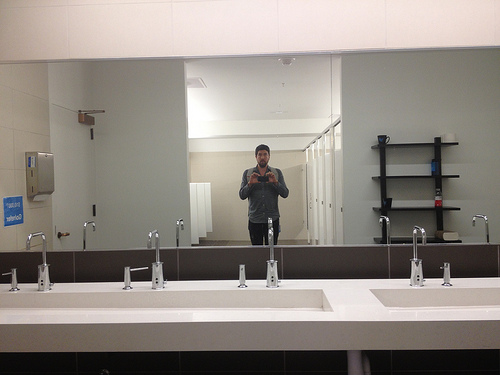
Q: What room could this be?
A: It is a bathroom.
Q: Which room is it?
A: It is a bathroom.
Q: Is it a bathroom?
A: Yes, it is a bathroom.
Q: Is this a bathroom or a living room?
A: It is a bathroom.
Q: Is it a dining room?
A: No, it is a bathroom.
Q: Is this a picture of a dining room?
A: No, the picture is showing a bathroom.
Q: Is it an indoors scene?
A: Yes, it is indoors.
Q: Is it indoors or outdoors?
A: It is indoors.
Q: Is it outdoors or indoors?
A: It is indoors.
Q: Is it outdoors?
A: No, it is indoors.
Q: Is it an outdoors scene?
A: No, it is indoors.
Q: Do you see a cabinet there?
A: No, there are no cabinets.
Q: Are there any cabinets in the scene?
A: No, there are no cabinets.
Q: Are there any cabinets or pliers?
A: No, there are no cabinets or pliers.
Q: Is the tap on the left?
A: Yes, the tap is on the left of the image.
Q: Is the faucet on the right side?
A: No, the faucet is on the left of the image.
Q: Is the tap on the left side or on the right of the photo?
A: The tap is on the left of the image.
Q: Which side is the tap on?
A: The tap is on the left of the image.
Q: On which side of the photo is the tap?
A: The tap is on the left of the image.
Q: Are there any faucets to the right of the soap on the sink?
A: Yes, there is a faucet to the right of the soap.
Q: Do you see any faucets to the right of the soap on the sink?
A: Yes, there is a faucet to the right of the soap.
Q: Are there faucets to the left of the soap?
A: No, the faucet is to the right of the soap.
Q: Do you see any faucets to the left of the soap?
A: No, the faucet is to the right of the soap.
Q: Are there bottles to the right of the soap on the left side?
A: No, there is a faucet to the right of the soap.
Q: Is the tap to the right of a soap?
A: Yes, the tap is to the right of a soap.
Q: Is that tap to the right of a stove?
A: No, the tap is to the right of a soap.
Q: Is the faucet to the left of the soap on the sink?
A: No, the faucet is to the right of the soap.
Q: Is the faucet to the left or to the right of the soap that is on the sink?
A: The faucet is to the right of the soap.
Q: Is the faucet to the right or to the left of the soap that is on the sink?
A: The faucet is to the right of the soap.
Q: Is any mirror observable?
A: Yes, there is a mirror.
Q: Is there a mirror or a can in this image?
A: Yes, there is a mirror.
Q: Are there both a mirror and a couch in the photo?
A: No, there is a mirror but no couches.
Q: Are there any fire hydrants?
A: No, there are no fire hydrants.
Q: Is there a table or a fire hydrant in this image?
A: No, there are no fire hydrants or tables.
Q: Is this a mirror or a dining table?
A: This is a mirror.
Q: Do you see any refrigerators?
A: No, there are no refrigerators.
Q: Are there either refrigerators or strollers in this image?
A: No, there are no refrigerators or strollers.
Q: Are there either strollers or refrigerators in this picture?
A: No, there are no refrigerators or strollers.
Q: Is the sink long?
A: Yes, the sink is long.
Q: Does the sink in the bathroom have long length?
A: Yes, the sink is long.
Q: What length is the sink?
A: The sink is long.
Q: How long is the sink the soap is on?
A: The sink is long.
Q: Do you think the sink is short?
A: No, the sink is long.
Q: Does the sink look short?
A: No, the sink is long.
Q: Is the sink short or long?
A: The sink is long.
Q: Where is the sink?
A: The sink is in the bathroom.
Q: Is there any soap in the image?
A: Yes, there is a soap.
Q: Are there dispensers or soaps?
A: Yes, there is a soap.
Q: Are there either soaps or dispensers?
A: Yes, there is a soap.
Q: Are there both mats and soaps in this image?
A: No, there is a soap but no mats.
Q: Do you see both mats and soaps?
A: No, there is a soap but no mats.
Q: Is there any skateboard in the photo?
A: No, there are no skateboards.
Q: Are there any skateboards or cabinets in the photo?
A: No, there are no skateboards or cabinets.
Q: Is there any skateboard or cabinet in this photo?
A: No, there are no skateboards or cabinets.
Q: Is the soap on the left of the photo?
A: Yes, the soap is on the left of the image.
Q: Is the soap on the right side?
A: No, the soap is on the left of the image.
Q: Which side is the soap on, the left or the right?
A: The soap is on the left of the image.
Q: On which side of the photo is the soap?
A: The soap is on the left of the image.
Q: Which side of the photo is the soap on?
A: The soap is on the left of the image.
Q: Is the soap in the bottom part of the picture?
A: Yes, the soap is in the bottom of the image.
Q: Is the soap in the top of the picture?
A: No, the soap is in the bottom of the image.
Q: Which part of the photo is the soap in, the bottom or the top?
A: The soap is in the bottom of the image.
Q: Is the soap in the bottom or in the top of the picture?
A: The soap is in the bottom of the image.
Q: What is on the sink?
A: The soap is on the sink.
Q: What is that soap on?
A: The soap is on the sink.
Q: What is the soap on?
A: The soap is on the sink.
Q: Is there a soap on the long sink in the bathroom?
A: Yes, there is a soap on the sink.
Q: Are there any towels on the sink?
A: No, there is a soap on the sink.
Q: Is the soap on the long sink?
A: Yes, the soap is on the sink.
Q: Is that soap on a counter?
A: No, the soap is on the sink.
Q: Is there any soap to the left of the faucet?
A: Yes, there is a soap to the left of the faucet.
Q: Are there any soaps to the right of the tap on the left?
A: No, the soap is to the left of the tap.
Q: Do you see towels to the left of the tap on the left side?
A: No, there is a soap to the left of the faucet.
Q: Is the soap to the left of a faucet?
A: Yes, the soap is to the left of a faucet.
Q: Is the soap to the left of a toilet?
A: No, the soap is to the left of a faucet.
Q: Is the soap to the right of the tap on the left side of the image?
A: No, the soap is to the left of the faucet.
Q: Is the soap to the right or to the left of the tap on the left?
A: The soap is to the left of the faucet.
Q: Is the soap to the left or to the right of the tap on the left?
A: The soap is to the left of the faucet.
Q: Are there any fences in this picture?
A: No, there are no fences.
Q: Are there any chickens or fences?
A: No, there are no fences or chickens.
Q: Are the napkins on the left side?
A: Yes, the napkins are on the left of the image.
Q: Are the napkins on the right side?
A: No, the napkins are on the left of the image.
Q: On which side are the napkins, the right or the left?
A: The napkins are on the left of the image.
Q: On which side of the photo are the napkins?
A: The napkins are on the left of the image.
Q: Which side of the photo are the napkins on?
A: The napkins are on the left of the image.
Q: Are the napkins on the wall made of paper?
A: Yes, the napkins are made of paper.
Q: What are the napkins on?
A: The napkins are on the wall.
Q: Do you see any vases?
A: No, there are no vases.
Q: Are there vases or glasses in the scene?
A: No, there are no vases or glasses.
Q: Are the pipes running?
A: Yes, the pipes are running.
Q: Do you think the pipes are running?
A: Yes, the pipes are running.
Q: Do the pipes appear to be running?
A: Yes, the pipes are running.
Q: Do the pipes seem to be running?
A: Yes, the pipes are running.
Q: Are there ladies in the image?
A: No, there are no ladies.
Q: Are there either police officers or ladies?
A: No, there are no ladies or police officers.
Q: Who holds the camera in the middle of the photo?
A: The man holds the camera.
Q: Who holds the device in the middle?
A: The man holds the camera.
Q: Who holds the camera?
A: The man holds the camera.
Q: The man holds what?
A: The man holds the camera.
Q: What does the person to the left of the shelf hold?
A: The man holds the camera.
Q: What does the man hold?
A: The man holds the camera.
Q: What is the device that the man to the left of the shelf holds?
A: The device is a camera.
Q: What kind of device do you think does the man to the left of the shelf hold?
A: The man holds the camera.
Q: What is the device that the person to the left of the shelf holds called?
A: The device is a camera.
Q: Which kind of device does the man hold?
A: The man holds the camera.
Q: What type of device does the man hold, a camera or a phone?
A: The man holds a camera.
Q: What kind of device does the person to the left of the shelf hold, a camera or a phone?
A: The man holds a camera.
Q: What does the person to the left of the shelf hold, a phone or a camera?
A: The man holds a camera.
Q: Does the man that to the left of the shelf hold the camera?
A: Yes, the man holds the camera.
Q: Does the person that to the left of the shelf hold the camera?
A: Yes, the man holds the camera.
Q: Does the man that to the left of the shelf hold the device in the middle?
A: Yes, the man holds the camera.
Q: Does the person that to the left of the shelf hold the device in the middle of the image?
A: Yes, the man holds the camera.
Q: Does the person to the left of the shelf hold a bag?
A: No, the man holds the camera.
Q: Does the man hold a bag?
A: No, the man holds the camera.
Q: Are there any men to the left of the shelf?
A: Yes, there is a man to the left of the shelf.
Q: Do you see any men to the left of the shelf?
A: Yes, there is a man to the left of the shelf.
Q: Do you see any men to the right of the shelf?
A: No, the man is to the left of the shelf.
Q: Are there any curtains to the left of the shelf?
A: No, there is a man to the left of the shelf.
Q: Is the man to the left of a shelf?
A: Yes, the man is to the left of a shelf.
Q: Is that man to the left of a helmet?
A: No, the man is to the left of a shelf.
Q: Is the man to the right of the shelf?
A: No, the man is to the left of the shelf.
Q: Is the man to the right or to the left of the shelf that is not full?
A: The man is to the left of the shelf.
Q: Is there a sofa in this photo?
A: No, there are no sofas.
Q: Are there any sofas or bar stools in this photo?
A: No, there are no sofas or bar stools.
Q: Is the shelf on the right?
A: Yes, the shelf is on the right of the image.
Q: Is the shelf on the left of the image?
A: No, the shelf is on the right of the image.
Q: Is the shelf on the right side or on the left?
A: The shelf is on the right of the image.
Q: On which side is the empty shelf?
A: The shelf is on the right of the image.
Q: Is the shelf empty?
A: Yes, the shelf is empty.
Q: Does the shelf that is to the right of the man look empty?
A: Yes, the shelf is empty.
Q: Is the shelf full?
A: No, the shelf is empty.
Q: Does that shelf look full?
A: No, the shelf is empty.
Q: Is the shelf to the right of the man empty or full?
A: The shelf is empty.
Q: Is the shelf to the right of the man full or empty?
A: The shelf is empty.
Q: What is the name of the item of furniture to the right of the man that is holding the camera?
A: The piece of furniture is a shelf.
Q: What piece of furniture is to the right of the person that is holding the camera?
A: The piece of furniture is a shelf.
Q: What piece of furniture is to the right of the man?
A: The piece of furniture is a shelf.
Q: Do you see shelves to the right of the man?
A: Yes, there is a shelf to the right of the man.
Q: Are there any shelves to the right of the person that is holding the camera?
A: Yes, there is a shelf to the right of the man.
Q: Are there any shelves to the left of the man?
A: No, the shelf is to the right of the man.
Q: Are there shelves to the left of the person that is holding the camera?
A: No, the shelf is to the right of the man.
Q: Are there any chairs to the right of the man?
A: No, there is a shelf to the right of the man.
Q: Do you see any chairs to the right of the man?
A: No, there is a shelf to the right of the man.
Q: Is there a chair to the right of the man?
A: No, there is a shelf to the right of the man.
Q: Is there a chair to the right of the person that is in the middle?
A: No, there is a shelf to the right of the man.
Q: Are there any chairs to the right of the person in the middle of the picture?
A: No, there is a shelf to the right of the man.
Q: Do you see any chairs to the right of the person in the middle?
A: No, there is a shelf to the right of the man.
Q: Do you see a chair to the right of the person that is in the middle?
A: No, there is a shelf to the right of the man.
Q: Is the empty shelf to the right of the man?
A: Yes, the shelf is to the right of the man.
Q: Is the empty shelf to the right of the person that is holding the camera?
A: Yes, the shelf is to the right of the man.